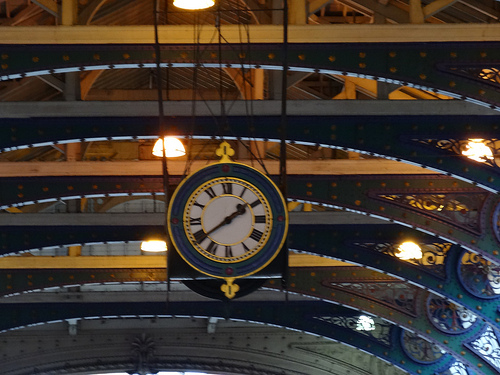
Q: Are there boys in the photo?
A: No, there are no boys.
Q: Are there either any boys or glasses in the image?
A: No, there are no boys or glasses.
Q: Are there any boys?
A: No, there are no boys.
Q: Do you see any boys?
A: No, there are no boys.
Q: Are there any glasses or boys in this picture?
A: No, there are no boys or glasses.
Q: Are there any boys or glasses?
A: No, there are no boys or glasses.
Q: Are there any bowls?
A: No, there are no bowls.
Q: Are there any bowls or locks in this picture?
A: No, there are no bowls or locks.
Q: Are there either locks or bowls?
A: No, there are no bowls or locks.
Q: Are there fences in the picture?
A: No, there are no fences.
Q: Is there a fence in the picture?
A: No, there are no fences.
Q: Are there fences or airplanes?
A: No, there are no fences or airplanes.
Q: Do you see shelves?
A: No, there are no shelves.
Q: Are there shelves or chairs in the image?
A: No, there are no shelves or chairs.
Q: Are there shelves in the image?
A: No, there are no shelves.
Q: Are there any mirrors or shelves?
A: No, there are no shelves or mirrors.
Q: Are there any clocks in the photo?
A: Yes, there is a clock.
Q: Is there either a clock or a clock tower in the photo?
A: Yes, there is a clock.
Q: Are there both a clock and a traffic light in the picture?
A: No, there is a clock but no traffic lights.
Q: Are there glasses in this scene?
A: No, there are no glasses.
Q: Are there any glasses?
A: No, there are no glasses.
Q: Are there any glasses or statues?
A: No, there are no glasses or statues.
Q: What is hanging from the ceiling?
A: The clock is hanging from the ceiling.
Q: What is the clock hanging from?
A: The clock is hanging from the ceiling.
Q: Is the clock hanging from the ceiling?
A: Yes, the clock is hanging from the ceiling.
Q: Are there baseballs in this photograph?
A: No, there are no baseballs.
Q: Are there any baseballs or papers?
A: No, there are no baseballs or papers.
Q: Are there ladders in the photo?
A: No, there are no ladders.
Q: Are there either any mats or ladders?
A: No, there are no ladders or mats.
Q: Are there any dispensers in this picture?
A: No, there are no dispensers.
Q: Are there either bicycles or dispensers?
A: No, there are no dispensers or bicycles.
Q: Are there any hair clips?
A: No, there are no hair clips.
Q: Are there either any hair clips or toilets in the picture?
A: No, there are no hair clips or toilets.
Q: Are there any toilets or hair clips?
A: No, there are no hair clips or toilets.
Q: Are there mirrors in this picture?
A: No, there are no mirrors.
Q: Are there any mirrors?
A: No, there are no mirrors.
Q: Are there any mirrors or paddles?
A: No, there are no mirrors or paddles.